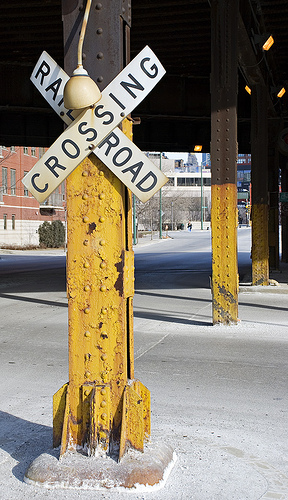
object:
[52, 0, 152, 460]
pole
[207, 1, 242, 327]
pole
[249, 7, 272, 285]
pole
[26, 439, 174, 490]
base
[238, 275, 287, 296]
base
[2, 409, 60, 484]
shadow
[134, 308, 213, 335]
shadow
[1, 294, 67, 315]
shadow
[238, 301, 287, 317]
shadow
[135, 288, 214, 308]
shadow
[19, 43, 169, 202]
sign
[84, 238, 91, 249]
rivets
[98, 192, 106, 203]
rivets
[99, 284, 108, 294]
rivets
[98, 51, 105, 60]
rivets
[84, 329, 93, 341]
rivets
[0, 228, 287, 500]
street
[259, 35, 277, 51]
lamp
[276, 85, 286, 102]
lamp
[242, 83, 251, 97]
lamp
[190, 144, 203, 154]
lamp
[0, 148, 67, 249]
building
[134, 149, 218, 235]
building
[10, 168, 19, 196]
window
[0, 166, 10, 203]
window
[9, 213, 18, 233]
window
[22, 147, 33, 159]
window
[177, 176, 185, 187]
window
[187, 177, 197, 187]
window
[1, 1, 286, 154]
ceiling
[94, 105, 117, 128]
letter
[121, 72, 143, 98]
letter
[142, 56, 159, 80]
letter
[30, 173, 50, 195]
letter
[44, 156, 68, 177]
letter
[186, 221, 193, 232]
person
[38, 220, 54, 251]
bush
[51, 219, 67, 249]
bush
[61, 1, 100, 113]
light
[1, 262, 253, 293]
shadow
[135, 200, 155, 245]
tree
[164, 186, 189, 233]
tree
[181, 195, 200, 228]
tree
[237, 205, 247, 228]
tree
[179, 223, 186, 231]
person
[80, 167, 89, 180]
bolt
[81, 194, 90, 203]
bolt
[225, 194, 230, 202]
bolt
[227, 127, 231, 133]
bolt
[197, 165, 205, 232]
post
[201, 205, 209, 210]
street sign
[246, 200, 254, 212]
traffic light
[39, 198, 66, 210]
balcony